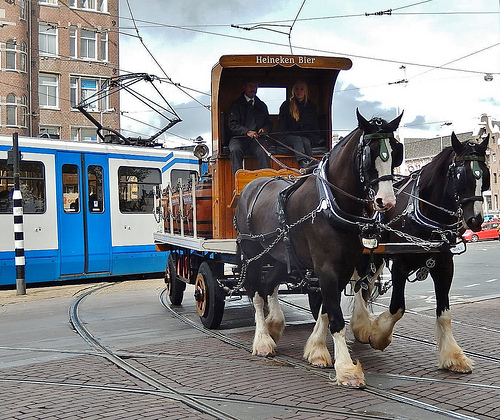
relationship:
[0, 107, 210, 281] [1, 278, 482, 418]
train beside sidewalk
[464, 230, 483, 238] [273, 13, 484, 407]
car on the right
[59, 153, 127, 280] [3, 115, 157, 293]
doors on transit system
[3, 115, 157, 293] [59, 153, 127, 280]
transit system with blue doors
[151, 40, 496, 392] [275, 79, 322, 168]
carriage with people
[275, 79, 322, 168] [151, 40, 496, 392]
people riding on carriage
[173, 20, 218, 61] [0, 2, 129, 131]
sky with building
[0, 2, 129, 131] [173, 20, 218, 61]
building in sky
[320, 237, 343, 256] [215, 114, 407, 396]
skin of horse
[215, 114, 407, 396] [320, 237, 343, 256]
horse with skin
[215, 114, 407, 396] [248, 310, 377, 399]
horse with feet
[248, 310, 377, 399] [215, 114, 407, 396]
feet of a horse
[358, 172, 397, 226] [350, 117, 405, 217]
bridle on face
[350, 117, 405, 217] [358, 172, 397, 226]
face with a bridle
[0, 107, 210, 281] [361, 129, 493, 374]
train behind horses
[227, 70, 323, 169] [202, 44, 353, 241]
people in horse carriage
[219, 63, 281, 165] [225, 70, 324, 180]
man riding in horse carriage